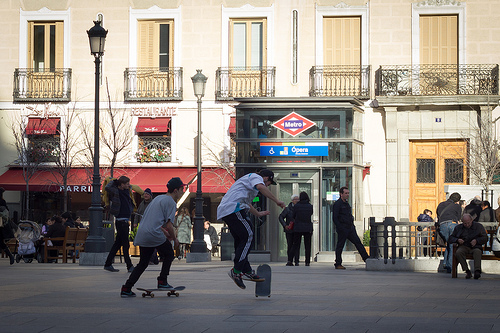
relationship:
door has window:
[408, 141, 463, 259] [436, 140, 468, 238]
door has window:
[408, 141, 463, 259] [411, 144, 437, 244]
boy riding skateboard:
[119, 174, 197, 300] [253, 263, 274, 304]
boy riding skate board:
[125, 173, 189, 299] [135, 280, 194, 302]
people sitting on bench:
[0, 212, 85, 263] [45, 224, 83, 262]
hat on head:
[167, 177, 189, 188] [166, 179, 185, 202]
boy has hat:
[120, 174, 187, 296] [167, 177, 189, 188]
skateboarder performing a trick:
[229, 167, 287, 209] [122, 251, 292, 333]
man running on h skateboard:
[121, 177, 183, 292] [136, 283, 185, 295]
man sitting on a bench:
[452, 199, 494, 281] [440, 222, 499, 247]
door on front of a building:
[280, 170, 317, 188] [356, 100, 474, 253]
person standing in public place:
[281, 191, 302, 265] [3, 166, 498, 329]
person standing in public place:
[294, 191, 312, 268] [3, 166, 498, 329]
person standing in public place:
[331, 187, 366, 271] [3, 166, 498, 329]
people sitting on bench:
[27, 207, 87, 257] [37, 225, 90, 261]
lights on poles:
[79, 19, 203, 94] [77, 125, 207, 181]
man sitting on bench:
[442, 211, 491, 282] [431, 219, 499, 269]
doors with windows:
[390, 114, 473, 260] [413, 153, 465, 188]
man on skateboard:
[106, 162, 194, 290] [139, 279, 185, 301]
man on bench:
[412, 179, 459, 288] [373, 185, 489, 278]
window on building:
[138, 17, 175, 98] [0, 1, 498, 259]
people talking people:
[278, 186, 317, 267] [277, 193, 313, 261]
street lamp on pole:
[65, 17, 121, 274] [90, 57, 100, 252]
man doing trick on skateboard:
[206, 159, 280, 289] [253, 259, 274, 301]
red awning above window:
[129, 109, 181, 144] [128, 110, 180, 164]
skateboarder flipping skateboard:
[214, 166, 284, 288] [254, 262, 271, 297]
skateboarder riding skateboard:
[115, 176, 190, 303] [130, 282, 185, 298]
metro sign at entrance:
[283, 120, 303, 127] [270, 170, 319, 265]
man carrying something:
[97, 172, 139, 281] [100, 174, 141, 196]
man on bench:
[449, 209, 484, 281] [435, 221, 499, 281]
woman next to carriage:
[38, 213, 67, 258] [15, 219, 46, 259]